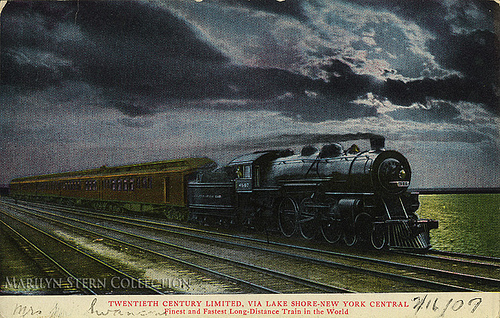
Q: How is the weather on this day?
A: It is cloudy.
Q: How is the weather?
A: It is cloudy.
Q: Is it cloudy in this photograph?
A: Yes, it is cloudy.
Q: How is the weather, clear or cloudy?
A: It is cloudy.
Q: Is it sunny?
A: No, it is cloudy.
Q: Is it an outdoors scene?
A: Yes, it is outdoors.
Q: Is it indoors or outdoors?
A: It is outdoors.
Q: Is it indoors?
A: No, it is outdoors.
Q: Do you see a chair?
A: No, there are no chairs.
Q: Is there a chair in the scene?
A: No, there are no chairs.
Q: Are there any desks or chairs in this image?
A: No, there are no chairs or desks.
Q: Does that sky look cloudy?
A: Yes, the sky is cloudy.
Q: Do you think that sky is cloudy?
A: Yes, the sky is cloudy.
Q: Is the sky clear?
A: No, the sky is cloudy.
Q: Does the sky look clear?
A: No, the sky is cloudy.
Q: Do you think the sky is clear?
A: No, the sky is cloudy.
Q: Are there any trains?
A: Yes, there is a train.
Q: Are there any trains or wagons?
A: Yes, there is a train.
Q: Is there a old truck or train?
A: Yes, there is an old train.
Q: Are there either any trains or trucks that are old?
A: Yes, the train is old.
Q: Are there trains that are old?
A: Yes, there is an old train.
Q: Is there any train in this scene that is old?
A: Yes, there is a train that is old.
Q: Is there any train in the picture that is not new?
A: Yes, there is a old train.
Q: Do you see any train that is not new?
A: Yes, there is a old train.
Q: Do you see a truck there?
A: No, there are no trucks.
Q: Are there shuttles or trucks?
A: No, there are no trucks or shuttles.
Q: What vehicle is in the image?
A: The vehicle is a train.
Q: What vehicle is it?
A: The vehicle is a train.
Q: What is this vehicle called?
A: This is a train.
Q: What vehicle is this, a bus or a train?
A: This is a train.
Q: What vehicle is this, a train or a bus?
A: This is a train.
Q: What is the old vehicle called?
A: The vehicle is a train.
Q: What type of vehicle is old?
A: The vehicle is a train.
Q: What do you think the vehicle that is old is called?
A: The vehicle is a train.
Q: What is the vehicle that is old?
A: The vehicle is a train.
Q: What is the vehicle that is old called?
A: The vehicle is a train.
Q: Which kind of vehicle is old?
A: The vehicle is a train.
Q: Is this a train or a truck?
A: This is a train.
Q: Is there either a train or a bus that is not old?
A: No, there is a train but it is old.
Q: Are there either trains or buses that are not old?
A: No, there is a train but it is old.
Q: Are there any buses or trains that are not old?
A: No, there is a train but it is old.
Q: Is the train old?
A: Yes, the train is old.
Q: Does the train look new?
A: No, the train is old.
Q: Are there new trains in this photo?
A: No, there is a train but it is old.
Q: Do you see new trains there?
A: No, there is a train but it is old.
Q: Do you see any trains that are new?
A: No, there is a train but it is old.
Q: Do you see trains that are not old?
A: No, there is a train but it is old.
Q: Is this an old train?
A: Yes, this is an old train.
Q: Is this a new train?
A: No, this is an old train.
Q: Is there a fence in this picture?
A: No, there are no fences.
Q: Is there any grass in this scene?
A: Yes, there is grass.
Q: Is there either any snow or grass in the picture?
A: Yes, there is grass.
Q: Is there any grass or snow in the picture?
A: Yes, there is grass.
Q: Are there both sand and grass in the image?
A: No, there is grass but no sand.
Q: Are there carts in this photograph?
A: No, there are no carts.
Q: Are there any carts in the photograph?
A: No, there are no carts.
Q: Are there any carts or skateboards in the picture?
A: No, there are no carts or skateboards.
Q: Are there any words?
A: Yes, there are words.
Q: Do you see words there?
A: Yes, there are words.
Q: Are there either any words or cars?
A: Yes, there are words.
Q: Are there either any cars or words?
A: Yes, there are words.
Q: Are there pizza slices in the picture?
A: No, there are no pizza slices.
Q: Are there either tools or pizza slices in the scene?
A: No, there are no pizza slices or tools.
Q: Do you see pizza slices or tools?
A: No, there are no pizza slices or tools.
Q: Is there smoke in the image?
A: Yes, there is smoke.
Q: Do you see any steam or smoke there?
A: Yes, there is smoke.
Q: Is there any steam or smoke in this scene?
A: Yes, there is smoke.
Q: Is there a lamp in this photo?
A: No, there are no lamps.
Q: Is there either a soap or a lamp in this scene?
A: No, there are no lamps or soaps.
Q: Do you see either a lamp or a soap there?
A: No, there are no lamps or soaps.